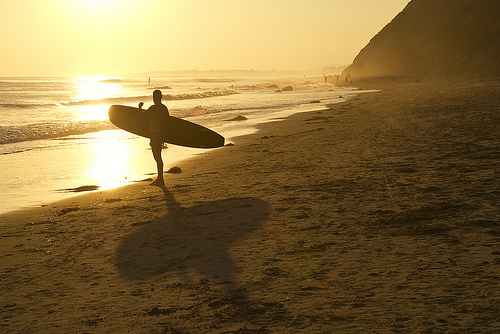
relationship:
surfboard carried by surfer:
[101, 109, 235, 158] [139, 85, 174, 185]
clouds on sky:
[23, 8, 46, 26] [167, 12, 343, 48]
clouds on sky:
[43, 21, 92, 46] [174, 12, 326, 50]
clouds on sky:
[4, 0, 413, 82] [163, 25, 315, 65]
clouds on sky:
[158, 8, 199, 22] [0, 0, 409, 218]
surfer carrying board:
[138, 90, 169, 186] [107, 103, 226, 150]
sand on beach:
[0, 102, 320, 211] [3, 87, 475, 332]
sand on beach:
[274, 110, 388, 220] [3, 87, 475, 332]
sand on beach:
[286, 160, 481, 307] [23, 103, 81, 190]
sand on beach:
[173, 259, 233, 289] [6, 89, 497, 316]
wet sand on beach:
[2, 78, 376, 218] [3, 87, 475, 332]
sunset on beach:
[71, 1, 128, 126] [8, 11, 478, 332]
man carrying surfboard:
[136, 86, 171, 190] [103, 99, 226, 153]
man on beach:
[138, 89, 169, 185] [3, 87, 475, 332]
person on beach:
[343, 76, 348, 85] [3, 87, 475, 332]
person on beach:
[323, 75, 326, 82] [3, 87, 475, 332]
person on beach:
[334, 73, 340, 81] [3, 87, 475, 332]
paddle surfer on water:
[147, 76, 153, 83] [0, 75, 380, 214]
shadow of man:
[113, 187, 269, 307] [139, 87, 172, 184]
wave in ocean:
[2, 105, 287, 142] [0, 71, 380, 215]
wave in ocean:
[1, 86, 240, 109] [0, 71, 380, 215]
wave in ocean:
[146, 84, 175, 90] [0, 71, 380, 215]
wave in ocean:
[98, 75, 143, 82] [0, 71, 380, 215]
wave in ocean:
[0, 77, 73, 84] [0, 71, 380, 215]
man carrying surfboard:
[138, 89, 169, 185] [108, 109, 228, 146]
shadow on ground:
[113, 187, 269, 307] [298, 178, 374, 253]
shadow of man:
[98, 181, 305, 326] [135, 90, 171, 183]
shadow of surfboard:
[98, 181, 305, 326] [110, 99, 224, 149]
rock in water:
[223, 107, 246, 122] [0, 55, 357, 153]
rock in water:
[163, 160, 180, 173] [0, 55, 357, 153]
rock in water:
[281, 81, 294, 92] [0, 55, 357, 153]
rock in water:
[263, 80, 277, 91] [0, 55, 357, 153]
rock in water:
[273, 87, 280, 94] [0, 55, 357, 153]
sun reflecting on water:
[68, 74, 132, 185] [0, 75, 380, 214]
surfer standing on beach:
[136, 87, 178, 192] [3, 87, 475, 332]